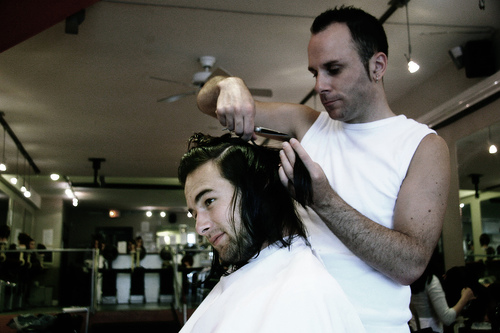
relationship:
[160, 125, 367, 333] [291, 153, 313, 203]
man has hair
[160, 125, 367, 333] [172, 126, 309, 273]
man cutting hair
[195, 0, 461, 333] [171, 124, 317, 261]
barber cutting hair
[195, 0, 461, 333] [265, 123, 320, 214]
barber holds hair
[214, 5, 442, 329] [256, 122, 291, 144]
barber holds comb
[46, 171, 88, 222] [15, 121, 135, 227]
lights on ceiling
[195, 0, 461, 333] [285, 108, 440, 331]
barber wears shirt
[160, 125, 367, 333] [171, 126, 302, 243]
man has hair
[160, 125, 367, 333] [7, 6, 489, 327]
man in hair salon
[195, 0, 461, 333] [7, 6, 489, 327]
barber in hair salon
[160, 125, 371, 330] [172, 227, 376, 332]
man wears apron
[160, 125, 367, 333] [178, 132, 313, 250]
man cut hair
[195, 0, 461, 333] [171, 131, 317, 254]
barber cut hair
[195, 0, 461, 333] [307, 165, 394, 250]
barber has hairy arm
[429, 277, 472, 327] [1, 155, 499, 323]
arm on background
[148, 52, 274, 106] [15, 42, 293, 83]
fan on background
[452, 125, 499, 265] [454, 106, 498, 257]
mirror on wall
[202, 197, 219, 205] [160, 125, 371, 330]
eye on man